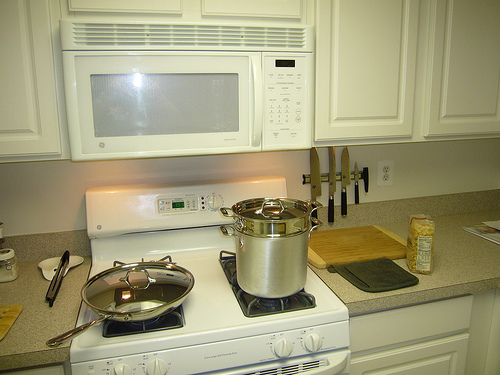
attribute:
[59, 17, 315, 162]
microwave — white, overhead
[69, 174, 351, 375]
stove — white, gas stove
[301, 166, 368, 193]
knife holder — wall mounted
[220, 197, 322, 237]
pot — stainless steel, for cooking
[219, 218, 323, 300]
pot — large, stainless steel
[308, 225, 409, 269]
chopping board — brown, wooden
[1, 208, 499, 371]
counter top — beige, laminated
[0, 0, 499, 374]
cabinets — white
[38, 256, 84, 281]
spoon rest — white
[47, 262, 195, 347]
pan — silver, frying pan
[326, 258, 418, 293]
hot pad — green, black, gray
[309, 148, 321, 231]
knife — displayed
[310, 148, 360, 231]
knives — displayed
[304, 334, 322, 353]
knob — white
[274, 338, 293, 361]
knob — white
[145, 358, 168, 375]
knob — white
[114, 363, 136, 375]
knob — white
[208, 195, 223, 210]
knob — white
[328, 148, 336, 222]
knife — displayed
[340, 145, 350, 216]
knife — displayed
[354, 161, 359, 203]
knife — displayed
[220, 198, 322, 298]
double boiler — stainless steel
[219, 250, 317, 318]
burner — black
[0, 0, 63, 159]
door — white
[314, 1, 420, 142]
door — white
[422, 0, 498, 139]
door — white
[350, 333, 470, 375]
door — white